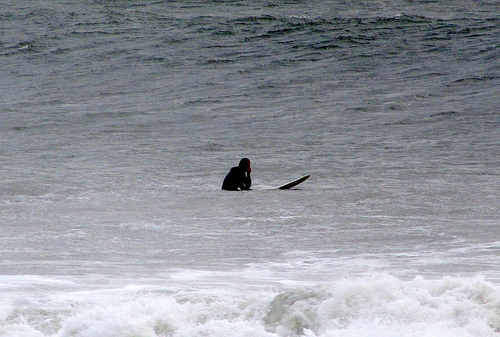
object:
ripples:
[344, 94, 479, 186]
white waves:
[1, 260, 498, 337]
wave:
[0, 0, 500, 337]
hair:
[239, 158, 250, 168]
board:
[279, 174, 311, 189]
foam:
[254, 181, 274, 196]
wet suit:
[221, 166, 251, 191]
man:
[222, 158, 252, 191]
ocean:
[2, 1, 499, 333]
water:
[1, 3, 498, 334]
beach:
[7, 4, 497, 334]